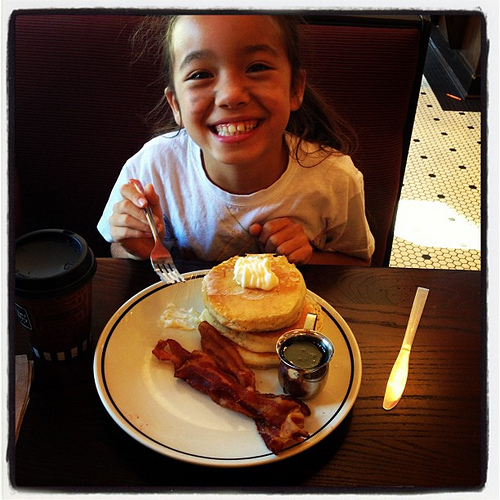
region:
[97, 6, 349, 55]
girl has brown hair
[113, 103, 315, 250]
girl has white shirt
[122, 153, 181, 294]
girl is holding fork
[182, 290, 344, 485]
white plate on table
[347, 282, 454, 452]
knife is on table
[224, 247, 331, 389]
pile of brown pancakes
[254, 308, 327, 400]
small cup of syrup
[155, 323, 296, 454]
brown bacon on plate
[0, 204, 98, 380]
plastic coffee cup on table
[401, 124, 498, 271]
white and black tile floor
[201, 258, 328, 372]
the stack of pancakes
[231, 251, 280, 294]
the pile of butter on the pancake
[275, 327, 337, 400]
the syrup in the teacup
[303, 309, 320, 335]
the handle of the small cup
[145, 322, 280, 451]
the bacon on the white plate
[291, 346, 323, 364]
the bubbles in the syrup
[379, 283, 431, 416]
the knif eon the table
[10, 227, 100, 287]
the balck lid to the coffee cup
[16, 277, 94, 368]
the cup on the table top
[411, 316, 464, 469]
the dark lines in the wooden table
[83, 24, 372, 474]
A child ready to eat pancakes and bacon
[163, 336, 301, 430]
bacon is on the plate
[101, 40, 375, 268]
the child is smiling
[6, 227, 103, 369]
the cup is plastic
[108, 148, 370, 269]
the shirt is white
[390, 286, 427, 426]
butter knife is on the table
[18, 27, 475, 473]
the scene is in a restarunt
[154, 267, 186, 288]
cream is on the fork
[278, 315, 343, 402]
the cup is mettalic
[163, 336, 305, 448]
the baccon is brown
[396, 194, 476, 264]
light reflection is on the floor